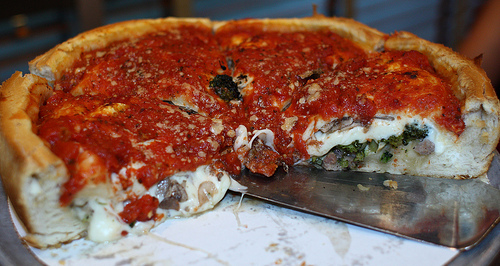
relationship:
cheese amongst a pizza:
[379, 127, 397, 133] [10, 10, 489, 220]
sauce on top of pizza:
[255, 37, 304, 61] [10, 10, 489, 220]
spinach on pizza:
[343, 145, 364, 158] [10, 10, 489, 220]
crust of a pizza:
[1, 70, 43, 196] [10, 10, 489, 220]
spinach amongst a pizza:
[349, 142, 367, 161] [10, 10, 489, 220]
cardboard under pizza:
[194, 219, 286, 259] [10, 10, 489, 220]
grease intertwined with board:
[283, 223, 349, 252] [194, 219, 286, 259]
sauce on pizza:
[255, 37, 304, 61] [10, 10, 489, 220]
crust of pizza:
[1, 70, 43, 196] [10, 10, 489, 220]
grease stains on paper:
[270, 216, 356, 262] [194, 219, 286, 259]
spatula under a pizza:
[277, 162, 499, 255] [10, 10, 489, 220]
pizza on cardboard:
[10, 10, 489, 220] [7, 196, 460, 265]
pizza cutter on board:
[231, 159, 496, 234] [3, 130, 498, 263]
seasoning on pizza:
[85, 50, 261, 139] [10, 10, 489, 220]